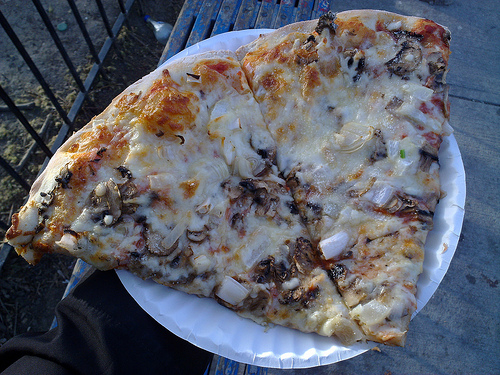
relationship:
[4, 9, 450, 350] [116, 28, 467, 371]
pizza on plate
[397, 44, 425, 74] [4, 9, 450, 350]
olive on pizza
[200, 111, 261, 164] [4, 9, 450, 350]
cheese on pizza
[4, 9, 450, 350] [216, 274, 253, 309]
pizza has onion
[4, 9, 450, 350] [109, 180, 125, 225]
pizza has mushroom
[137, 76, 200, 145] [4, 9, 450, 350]
bubble on pizza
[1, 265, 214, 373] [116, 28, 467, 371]
arm holding plate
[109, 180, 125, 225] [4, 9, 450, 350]
mushroom on pizza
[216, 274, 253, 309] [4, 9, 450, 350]
onion on pizza